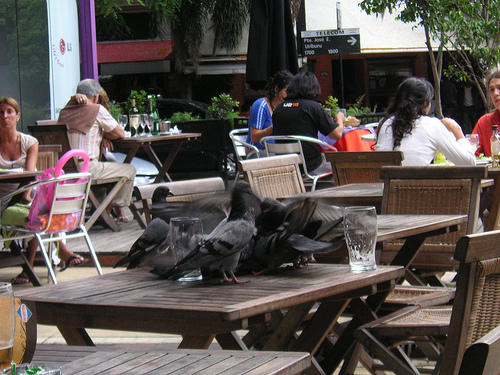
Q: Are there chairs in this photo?
A: Yes, there is a chair.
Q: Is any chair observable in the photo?
A: Yes, there is a chair.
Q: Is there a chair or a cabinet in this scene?
A: Yes, there is a chair.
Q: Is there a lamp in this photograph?
A: No, there are no lamps.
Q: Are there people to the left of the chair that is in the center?
A: Yes, there is a person to the left of the chair.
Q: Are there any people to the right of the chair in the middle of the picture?
A: No, the person is to the left of the chair.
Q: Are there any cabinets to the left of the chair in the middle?
A: No, there is a person to the left of the chair.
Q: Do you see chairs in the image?
A: Yes, there is a chair.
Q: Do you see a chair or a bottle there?
A: Yes, there is a chair.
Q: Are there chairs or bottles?
A: Yes, there is a chair.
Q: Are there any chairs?
A: Yes, there is a chair.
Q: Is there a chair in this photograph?
A: Yes, there is a chair.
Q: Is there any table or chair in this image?
A: Yes, there is a chair.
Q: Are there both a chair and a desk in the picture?
A: No, there is a chair but no desks.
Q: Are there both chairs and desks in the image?
A: No, there is a chair but no desks.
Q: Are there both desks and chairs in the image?
A: No, there is a chair but no desks.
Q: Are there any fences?
A: No, there are no fences.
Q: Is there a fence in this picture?
A: No, there are no fences.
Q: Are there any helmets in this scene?
A: No, there are no helmets.